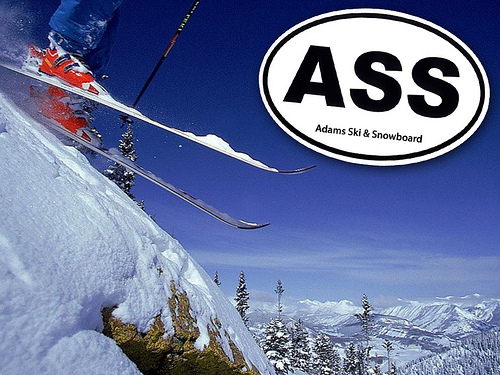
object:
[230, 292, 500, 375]
mountain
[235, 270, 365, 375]
trees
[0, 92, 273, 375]
hill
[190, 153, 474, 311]
sky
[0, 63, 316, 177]
ski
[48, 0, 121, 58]
pants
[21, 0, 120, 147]
man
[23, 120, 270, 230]
skis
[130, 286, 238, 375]
rock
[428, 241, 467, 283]
cloud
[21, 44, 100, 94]
boots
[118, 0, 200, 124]
ski pole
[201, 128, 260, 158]
snow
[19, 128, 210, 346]
slope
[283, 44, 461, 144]
logo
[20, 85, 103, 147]
shoe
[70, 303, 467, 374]
ground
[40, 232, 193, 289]
snow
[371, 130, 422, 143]
snowboard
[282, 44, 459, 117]
ass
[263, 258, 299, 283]
clouds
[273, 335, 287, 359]
snow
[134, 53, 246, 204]
air